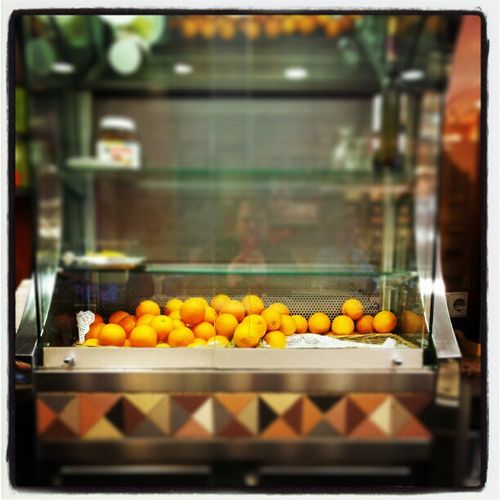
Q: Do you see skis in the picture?
A: No, there are no skis.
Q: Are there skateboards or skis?
A: No, there are no skis or skateboards.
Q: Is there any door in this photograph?
A: Yes, there is a door.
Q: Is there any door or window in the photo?
A: Yes, there is a door.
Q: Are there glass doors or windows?
A: Yes, there is a glass door.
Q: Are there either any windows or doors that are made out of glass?
A: Yes, the door is made of glass.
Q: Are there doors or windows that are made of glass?
A: Yes, the door is made of glass.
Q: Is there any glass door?
A: Yes, there is a door that is made of glass.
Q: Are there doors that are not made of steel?
A: Yes, there is a door that is made of glass.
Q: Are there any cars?
A: No, there are no cars.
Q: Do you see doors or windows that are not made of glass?
A: No, there is a door but it is made of glass.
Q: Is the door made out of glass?
A: Yes, the door is made of glass.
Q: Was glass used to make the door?
A: Yes, the door is made of glass.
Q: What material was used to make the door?
A: The door is made of glass.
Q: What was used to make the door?
A: The door is made of glass.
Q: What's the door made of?
A: The door is made of glass.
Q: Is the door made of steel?
A: No, the door is made of glass.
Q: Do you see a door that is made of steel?
A: No, there is a door but it is made of glass.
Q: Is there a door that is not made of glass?
A: No, there is a door but it is made of glass.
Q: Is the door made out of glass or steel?
A: The door is made of glass.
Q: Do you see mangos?
A: No, there are no mangos.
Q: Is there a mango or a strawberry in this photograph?
A: No, there are no mangoes or strawberries.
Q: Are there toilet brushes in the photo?
A: No, there are no toilet brushes.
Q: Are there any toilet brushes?
A: No, there are no toilet brushes.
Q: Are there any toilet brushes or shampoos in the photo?
A: No, there are no toilet brushes or shampoos.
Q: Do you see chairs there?
A: No, there are no chairs.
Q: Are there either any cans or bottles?
A: Yes, there is a bottle.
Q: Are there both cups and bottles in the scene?
A: Yes, there are both a bottle and a cup.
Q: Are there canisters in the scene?
A: No, there are no canisters.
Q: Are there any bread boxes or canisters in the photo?
A: No, there are no canisters or bread boxes.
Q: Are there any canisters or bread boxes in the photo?
A: No, there are no canisters or bread boxes.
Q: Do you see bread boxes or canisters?
A: No, there are no canisters or bread boxes.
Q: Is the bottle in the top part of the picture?
A: Yes, the bottle is in the top of the image.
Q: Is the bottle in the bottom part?
A: No, the bottle is in the top of the image.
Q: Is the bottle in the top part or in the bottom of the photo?
A: The bottle is in the top of the image.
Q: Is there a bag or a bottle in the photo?
A: Yes, there is a bottle.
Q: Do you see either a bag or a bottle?
A: Yes, there is a bottle.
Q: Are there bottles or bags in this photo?
A: Yes, there is a bottle.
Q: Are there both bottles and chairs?
A: No, there is a bottle but no chairs.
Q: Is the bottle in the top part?
A: Yes, the bottle is in the top of the image.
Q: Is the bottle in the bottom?
A: No, the bottle is in the top of the image.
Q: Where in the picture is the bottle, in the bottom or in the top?
A: The bottle is in the top of the image.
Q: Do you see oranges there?
A: Yes, there are oranges.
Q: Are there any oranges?
A: Yes, there are oranges.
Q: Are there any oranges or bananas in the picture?
A: Yes, there are oranges.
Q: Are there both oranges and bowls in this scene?
A: No, there are oranges but no bowls.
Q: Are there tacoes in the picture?
A: No, there are no tacoes.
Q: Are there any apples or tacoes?
A: No, there are no tacoes or apples.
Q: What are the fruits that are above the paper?
A: The fruits are oranges.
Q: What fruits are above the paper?
A: The fruits are oranges.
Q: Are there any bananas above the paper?
A: No, there are oranges above the paper.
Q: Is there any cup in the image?
A: Yes, there is a cup.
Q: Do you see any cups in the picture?
A: Yes, there is a cup.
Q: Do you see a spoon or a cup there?
A: Yes, there is a cup.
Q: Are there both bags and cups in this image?
A: No, there is a cup but no bags.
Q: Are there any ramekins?
A: No, there are no ramekins.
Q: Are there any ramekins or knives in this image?
A: No, there are no ramekins or knives.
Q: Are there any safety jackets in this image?
A: No, there are no safety jackets.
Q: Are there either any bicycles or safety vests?
A: No, there are no safety vests or bicycles.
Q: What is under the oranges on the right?
A: The paper is under the oranges.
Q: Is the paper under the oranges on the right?
A: Yes, the paper is under the oranges.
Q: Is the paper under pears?
A: No, the paper is under the oranges.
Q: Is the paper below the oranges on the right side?
A: Yes, the paper is below the oranges.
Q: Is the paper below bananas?
A: No, the paper is below the oranges.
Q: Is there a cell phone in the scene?
A: Yes, there is a cell phone.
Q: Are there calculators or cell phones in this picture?
A: Yes, there is a cell phone.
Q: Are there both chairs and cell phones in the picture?
A: No, there is a cell phone but no chairs.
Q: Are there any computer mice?
A: No, there are no computer mice.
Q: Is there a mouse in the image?
A: No, there are no computer mice.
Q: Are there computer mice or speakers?
A: No, there are no computer mice or speakers.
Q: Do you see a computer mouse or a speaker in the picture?
A: No, there are no computer mice or speakers.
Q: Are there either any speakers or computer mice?
A: No, there are no computer mice or speakers.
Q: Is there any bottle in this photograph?
A: Yes, there is a bottle.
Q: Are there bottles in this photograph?
A: Yes, there is a bottle.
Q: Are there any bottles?
A: Yes, there is a bottle.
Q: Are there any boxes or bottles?
A: Yes, there is a bottle.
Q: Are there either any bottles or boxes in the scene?
A: Yes, there is a bottle.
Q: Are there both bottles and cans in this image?
A: No, there is a bottle but no cans.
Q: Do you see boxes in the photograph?
A: No, there are no boxes.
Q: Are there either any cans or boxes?
A: No, there are no boxes or cans.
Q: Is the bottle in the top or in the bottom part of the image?
A: The bottle is in the top of the image.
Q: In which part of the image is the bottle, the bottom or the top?
A: The bottle is in the top of the image.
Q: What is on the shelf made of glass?
A: The bottle is on the shelf.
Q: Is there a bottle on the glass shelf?
A: Yes, there is a bottle on the shelf.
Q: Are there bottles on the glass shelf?
A: Yes, there is a bottle on the shelf.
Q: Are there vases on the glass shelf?
A: No, there is a bottle on the shelf.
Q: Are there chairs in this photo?
A: No, there are no chairs.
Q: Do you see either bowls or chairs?
A: No, there are no chairs or bowls.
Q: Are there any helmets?
A: No, there are no helmets.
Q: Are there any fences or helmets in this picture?
A: No, there are no helmets or fences.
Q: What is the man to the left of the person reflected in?
A: The man is reflected in the glass.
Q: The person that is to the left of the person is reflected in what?
A: The man is reflected in the glass.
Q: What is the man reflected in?
A: The man is reflected in the glass.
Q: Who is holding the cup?
A: The man is holding the cup.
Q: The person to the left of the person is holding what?
A: The man is holding the cup.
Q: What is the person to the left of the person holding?
A: The man is holding the cup.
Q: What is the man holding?
A: The man is holding the cup.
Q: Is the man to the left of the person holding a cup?
A: Yes, the man is holding a cup.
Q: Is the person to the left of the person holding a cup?
A: Yes, the man is holding a cup.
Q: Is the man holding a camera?
A: No, the man is holding a cup.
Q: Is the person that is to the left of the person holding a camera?
A: No, the man is holding a cup.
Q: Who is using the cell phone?
A: The man is using the cell phone.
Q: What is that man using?
A: The man is using a cellphone.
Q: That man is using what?
A: The man is using a cellphone.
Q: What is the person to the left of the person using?
A: The man is using a cellphone.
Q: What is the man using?
A: The man is using a cellphone.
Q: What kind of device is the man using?
A: The man is using a cellphone.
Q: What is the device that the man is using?
A: The device is a cell phone.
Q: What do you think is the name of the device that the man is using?
A: The device is a cell phone.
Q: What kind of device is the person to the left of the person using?
A: The man is using a cellphone.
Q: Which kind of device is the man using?
A: The man is using a cellphone.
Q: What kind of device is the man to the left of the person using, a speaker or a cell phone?
A: The man is using a cell phone.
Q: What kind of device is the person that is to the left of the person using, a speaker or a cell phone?
A: The man is using a cell phone.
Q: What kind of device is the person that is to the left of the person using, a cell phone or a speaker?
A: The man is using a cell phone.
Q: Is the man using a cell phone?
A: Yes, the man is using a cell phone.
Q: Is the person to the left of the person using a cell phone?
A: Yes, the man is using a cell phone.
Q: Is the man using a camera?
A: No, the man is using a cell phone.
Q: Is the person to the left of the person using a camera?
A: No, the man is using a cell phone.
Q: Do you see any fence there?
A: No, there are no fences.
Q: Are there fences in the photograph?
A: No, there are no fences.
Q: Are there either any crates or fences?
A: No, there are no fences or crates.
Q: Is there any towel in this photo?
A: No, there are no towels.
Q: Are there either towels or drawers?
A: No, there are no towels or drawers.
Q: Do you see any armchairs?
A: No, there are no armchairs.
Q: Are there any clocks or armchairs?
A: No, there are no armchairs or clocks.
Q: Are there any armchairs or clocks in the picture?
A: No, there are no armchairs or clocks.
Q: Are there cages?
A: No, there are no cages.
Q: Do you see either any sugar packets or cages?
A: No, there are no cages or sugar packets.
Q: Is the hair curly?
A: Yes, the hair is curly.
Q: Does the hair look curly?
A: Yes, the hair is curly.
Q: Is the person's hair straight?
A: No, the hair is curly.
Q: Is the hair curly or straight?
A: The hair is curly.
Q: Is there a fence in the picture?
A: No, there are no fences.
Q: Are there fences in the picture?
A: No, there are no fences.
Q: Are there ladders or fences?
A: No, there are no fences or ladders.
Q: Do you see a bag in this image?
A: No, there are no bags.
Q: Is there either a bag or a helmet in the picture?
A: No, there are no bags or helmets.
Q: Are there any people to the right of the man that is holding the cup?
A: Yes, there is a person to the right of the man.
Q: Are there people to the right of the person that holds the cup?
A: Yes, there is a person to the right of the man.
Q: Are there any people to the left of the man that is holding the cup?
A: No, the person is to the right of the man.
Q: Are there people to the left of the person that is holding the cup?
A: No, the person is to the right of the man.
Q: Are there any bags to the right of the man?
A: No, there is a person to the right of the man.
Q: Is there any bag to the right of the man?
A: No, there is a person to the right of the man.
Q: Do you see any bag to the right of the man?
A: No, there is a person to the right of the man.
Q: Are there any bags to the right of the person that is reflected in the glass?
A: No, there is a person to the right of the man.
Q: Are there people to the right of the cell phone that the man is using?
A: Yes, there is a person to the right of the cellphone.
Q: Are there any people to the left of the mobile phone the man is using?
A: No, the person is to the right of the mobile phone.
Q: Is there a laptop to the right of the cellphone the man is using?
A: No, there is a person to the right of the cell phone.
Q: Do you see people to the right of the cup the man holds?
A: Yes, there is a person to the right of the cup.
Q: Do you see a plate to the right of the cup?
A: No, there is a person to the right of the cup.